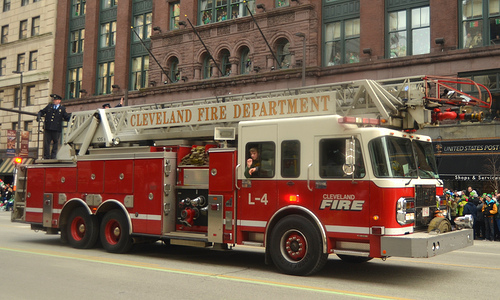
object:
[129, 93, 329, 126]
writing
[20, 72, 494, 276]
fire truck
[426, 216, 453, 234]
hose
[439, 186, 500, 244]
people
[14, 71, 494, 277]
truck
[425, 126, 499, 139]
wall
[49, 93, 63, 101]
hat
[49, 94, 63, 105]
head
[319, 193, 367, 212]
sign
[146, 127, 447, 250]
tomato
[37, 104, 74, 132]
jacket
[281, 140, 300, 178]
window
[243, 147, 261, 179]
person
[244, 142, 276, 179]
window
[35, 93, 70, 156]
fireman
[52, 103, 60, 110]
shirt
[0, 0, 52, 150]
wall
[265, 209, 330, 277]
wheel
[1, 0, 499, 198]
building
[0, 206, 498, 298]
street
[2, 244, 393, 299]
lines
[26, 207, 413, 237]
stripe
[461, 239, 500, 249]
sidewalk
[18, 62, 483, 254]
ladder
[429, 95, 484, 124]
hose